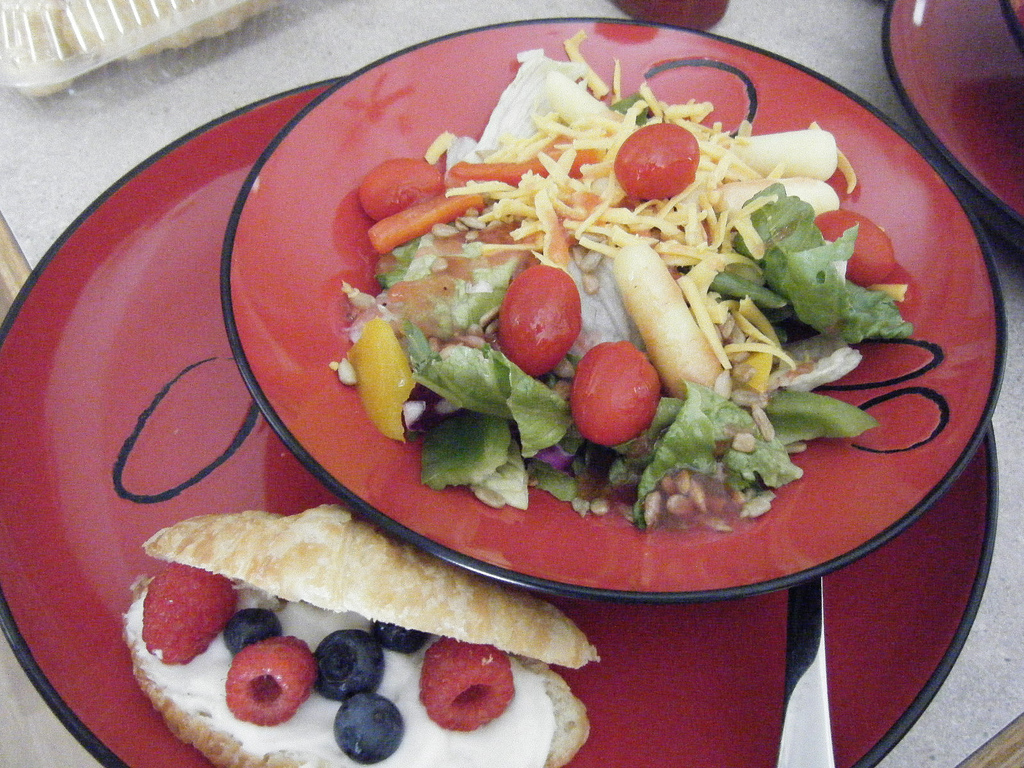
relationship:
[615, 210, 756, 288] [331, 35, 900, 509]
cheese in salad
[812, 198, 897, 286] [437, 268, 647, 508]
tomato on salad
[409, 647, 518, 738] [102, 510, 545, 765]
raspberry on tart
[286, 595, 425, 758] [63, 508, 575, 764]
blueberries on tart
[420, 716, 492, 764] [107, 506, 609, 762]
cream on tart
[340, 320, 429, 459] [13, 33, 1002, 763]
pepper on plates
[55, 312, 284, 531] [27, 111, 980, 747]
design on plate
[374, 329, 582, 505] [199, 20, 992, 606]
lettuce on plate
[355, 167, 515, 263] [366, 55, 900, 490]
carrot on salad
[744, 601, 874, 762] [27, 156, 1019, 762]
utensil on plate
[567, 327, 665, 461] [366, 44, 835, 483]
olive on salad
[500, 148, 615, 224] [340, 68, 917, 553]
cheese on salad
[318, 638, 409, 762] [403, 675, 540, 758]
olives on cream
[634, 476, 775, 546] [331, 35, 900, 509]
salad dressing on salad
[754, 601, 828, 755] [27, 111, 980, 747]
utensil on plate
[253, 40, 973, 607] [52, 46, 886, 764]
bowl on plate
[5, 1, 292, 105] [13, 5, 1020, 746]
container on counter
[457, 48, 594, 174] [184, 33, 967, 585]
lettuce in bowl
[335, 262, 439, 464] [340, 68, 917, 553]
food on salad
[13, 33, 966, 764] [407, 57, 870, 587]
plates of food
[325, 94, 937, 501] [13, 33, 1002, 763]
food on a plates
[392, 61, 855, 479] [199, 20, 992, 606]
salad on a plate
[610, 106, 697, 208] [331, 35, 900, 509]
tomato on top of salad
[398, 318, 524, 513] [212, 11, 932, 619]
lettuce on top of plate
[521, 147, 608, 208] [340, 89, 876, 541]
cheese on top of salad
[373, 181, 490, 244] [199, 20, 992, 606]
carrot on top of plate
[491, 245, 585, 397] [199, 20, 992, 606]
tomato on top of plate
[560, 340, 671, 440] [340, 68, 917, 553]
tomato on top of salad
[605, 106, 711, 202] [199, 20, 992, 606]
tomato on top of plate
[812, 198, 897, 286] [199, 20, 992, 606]
tomato on top of plate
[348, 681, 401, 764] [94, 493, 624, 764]
blueberry on top of bread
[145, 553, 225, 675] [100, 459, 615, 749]
raspberry on top of bread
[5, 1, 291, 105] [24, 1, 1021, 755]
container on top of table